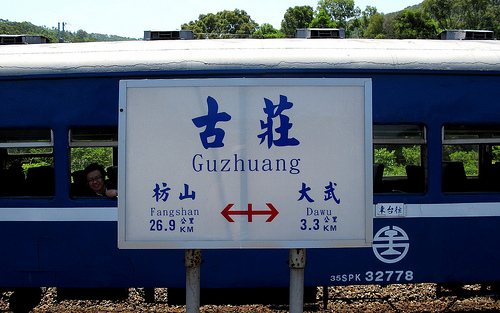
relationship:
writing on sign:
[142, 88, 356, 238] [116, 75, 390, 304]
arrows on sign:
[217, 197, 282, 231] [116, 75, 390, 304]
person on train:
[77, 160, 119, 197] [1, 25, 498, 288]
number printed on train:
[326, 266, 419, 283] [1, 25, 498, 288]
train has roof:
[1, 25, 498, 288] [1, 32, 499, 68]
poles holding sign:
[168, 245, 326, 311] [116, 75, 390, 304]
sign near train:
[116, 75, 390, 304] [1, 25, 498, 288]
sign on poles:
[116, 75, 390, 304] [168, 245, 326, 311]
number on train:
[326, 266, 419, 283] [1, 25, 498, 288]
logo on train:
[372, 225, 413, 263] [1, 25, 498, 288]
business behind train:
[52, 19, 78, 36] [1, 25, 498, 288]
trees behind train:
[1, 5, 494, 37] [1, 25, 498, 288]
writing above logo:
[142, 88, 356, 238] [372, 225, 413, 263]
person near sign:
[77, 160, 119, 197] [116, 75, 390, 304]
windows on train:
[0, 120, 500, 201] [1, 25, 498, 288]